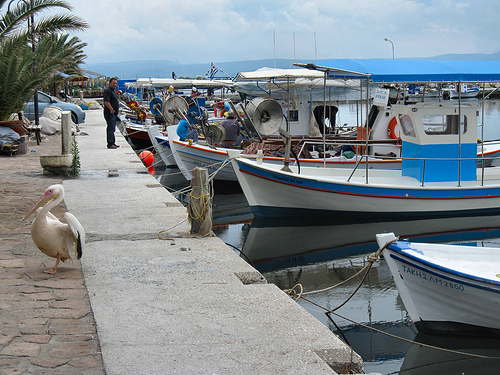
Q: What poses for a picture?
A: A pelican.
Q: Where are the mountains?
A: They are in the background.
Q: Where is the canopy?
A: On the boat.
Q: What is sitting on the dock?
A: A pelican.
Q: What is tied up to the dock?
A: Boats.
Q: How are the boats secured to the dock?
A: Rope.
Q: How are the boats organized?
A: In a row.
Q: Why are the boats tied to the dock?
A: Secured in place.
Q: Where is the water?
A: Under the boats.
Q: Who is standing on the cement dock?
A: A man.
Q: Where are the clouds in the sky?
A: Over the mountains.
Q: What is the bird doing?
A: Standing on the cement.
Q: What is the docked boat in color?
A: Red, white and blue.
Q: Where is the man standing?
A: On a boat dock.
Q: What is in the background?
A: Blue sky and white clouds.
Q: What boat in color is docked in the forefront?
A: Red, white and blue boat.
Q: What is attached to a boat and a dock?
A: Ropes.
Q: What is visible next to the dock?
A: A boat.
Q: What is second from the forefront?
A: A boat.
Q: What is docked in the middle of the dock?
A: A boat.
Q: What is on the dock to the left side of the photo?
A: Bird.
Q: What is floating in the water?
A: Boats.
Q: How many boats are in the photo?
A: Seven.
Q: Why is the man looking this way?
A: Looking at the bird.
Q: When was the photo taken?
A: Daytime.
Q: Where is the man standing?
A: On the dock.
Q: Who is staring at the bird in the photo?
A: The man.